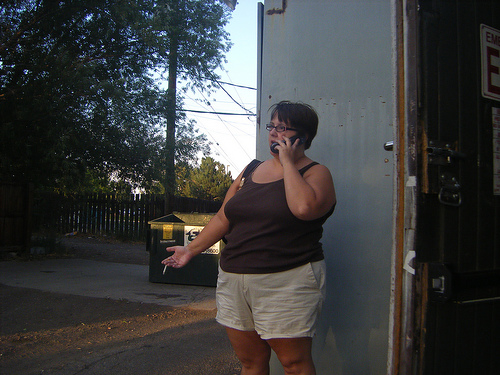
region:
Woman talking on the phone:
[156, 100, 338, 374]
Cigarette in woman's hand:
[153, 247, 195, 274]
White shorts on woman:
[212, 252, 329, 340]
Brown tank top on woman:
[216, 159, 337, 275]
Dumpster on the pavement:
[145, 218, 220, 293]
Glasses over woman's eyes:
[263, 114, 293, 138]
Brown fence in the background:
[36, 182, 216, 250]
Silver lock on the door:
[382, 134, 397, 161]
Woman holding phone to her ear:
[262, 97, 324, 157]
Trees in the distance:
[166, 153, 234, 209]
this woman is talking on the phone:
[144, 49, 379, 367]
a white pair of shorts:
[194, 243, 389, 348]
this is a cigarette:
[152, 249, 177, 281]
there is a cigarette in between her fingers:
[144, 230, 210, 295]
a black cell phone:
[260, 126, 311, 157]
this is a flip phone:
[265, 124, 312, 163]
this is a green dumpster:
[136, 206, 237, 287]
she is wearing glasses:
[256, 119, 326, 137]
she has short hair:
[239, 60, 326, 172]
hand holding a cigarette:
[148, 234, 205, 282]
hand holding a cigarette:
[146, 230, 191, 279]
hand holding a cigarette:
[146, 230, 202, 290]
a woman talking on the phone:
[245, 92, 317, 187]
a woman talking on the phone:
[248, 91, 323, 181]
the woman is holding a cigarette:
[158, 244, 189, 278]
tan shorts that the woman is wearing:
[211, 255, 318, 342]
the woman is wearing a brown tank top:
[228, 163, 321, 271]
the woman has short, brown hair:
[269, 94, 324, 125]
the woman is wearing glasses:
[266, 117, 297, 133]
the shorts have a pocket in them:
[304, 260, 328, 290]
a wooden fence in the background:
[76, 185, 147, 238]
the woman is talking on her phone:
[271, 131, 311, 153]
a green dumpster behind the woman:
[152, 208, 219, 286]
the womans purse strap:
[236, 153, 253, 188]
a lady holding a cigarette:
[155, 91, 310, 371]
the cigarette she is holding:
[158, 258, 166, 273]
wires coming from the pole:
[170, 62, 258, 128]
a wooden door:
[390, 7, 492, 363]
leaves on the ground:
[31, 295, 181, 340]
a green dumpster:
[140, 210, 220, 282]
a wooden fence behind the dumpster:
[26, 190, 211, 235]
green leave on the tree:
[58, 81, 108, 126]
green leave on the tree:
[68, 108, 108, 148]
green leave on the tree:
[181, 178, 216, 198]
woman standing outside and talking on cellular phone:
[153, 96, 340, 373]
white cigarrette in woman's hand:
[160, 259, 170, 277]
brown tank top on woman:
[214, 155, 340, 278]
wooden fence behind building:
[45, 185, 222, 244]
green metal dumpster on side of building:
[144, 208, 220, 294]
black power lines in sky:
[153, 60, 258, 175]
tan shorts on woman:
[209, 255, 330, 348]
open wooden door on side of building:
[381, 0, 446, 373]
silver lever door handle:
[379, 136, 396, 155]